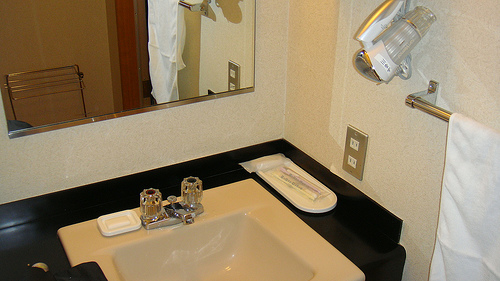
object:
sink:
[57, 177, 366, 281]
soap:
[105, 215, 131, 231]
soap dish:
[97, 210, 142, 237]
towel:
[428, 112, 500, 281]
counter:
[0, 137, 406, 281]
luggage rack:
[3, 64, 88, 120]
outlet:
[342, 123, 370, 181]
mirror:
[0, 0, 258, 139]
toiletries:
[238, 153, 337, 214]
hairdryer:
[353, 0, 437, 86]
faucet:
[162, 195, 196, 225]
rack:
[405, 80, 454, 122]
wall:
[284, 0, 499, 281]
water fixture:
[140, 176, 204, 230]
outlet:
[227, 59, 241, 92]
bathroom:
[0, 0, 500, 281]